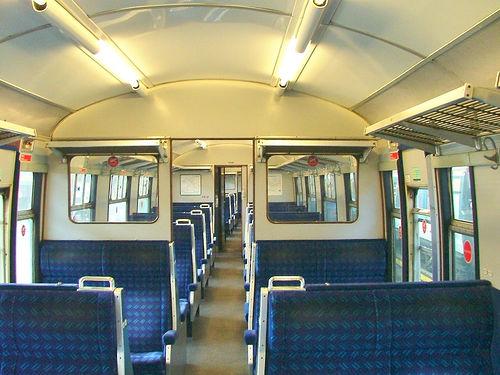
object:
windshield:
[71, 157, 161, 221]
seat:
[246, 238, 391, 334]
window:
[61, 146, 166, 228]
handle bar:
[79, 276, 116, 291]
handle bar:
[175, 219, 191, 226]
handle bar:
[191, 210, 204, 215]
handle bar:
[199, 204, 210, 208]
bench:
[261, 273, 498, 373]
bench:
[1, 276, 125, 373]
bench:
[173, 218, 201, 337]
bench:
[171, 203, 218, 274]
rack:
[364, 84, 500, 154]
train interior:
[160, 151, 368, 281]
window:
[264, 146, 363, 224]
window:
[388, 215, 407, 282]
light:
[276, 38, 308, 86]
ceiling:
[0, 0, 499, 142]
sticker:
[308, 156, 319, 167]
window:
[66, 150, 161, 225]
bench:
[31, 238, 176, 372]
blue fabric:
[0, 287, 115, 374]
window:
[17, 172, 37, 210]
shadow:
[190, 315, 208, 341]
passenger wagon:
[0, 0, 499, 372]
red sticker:
[462, 240, 472, 264]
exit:
[0, 149, 12, 288]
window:
[442, 166, 475, 232]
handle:
[268, 275, 306, 292]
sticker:
[19, 154, 32, 161]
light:
[95, 41, 141, 89]